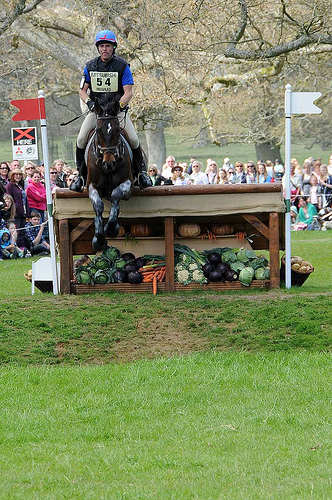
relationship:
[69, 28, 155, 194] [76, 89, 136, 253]
man riding horse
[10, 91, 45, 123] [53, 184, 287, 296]
red flag on hurdle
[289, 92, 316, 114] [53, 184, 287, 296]
flag on hurdle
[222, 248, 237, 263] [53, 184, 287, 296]
vegetable under hurdle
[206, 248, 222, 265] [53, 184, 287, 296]
vegetable under hurdle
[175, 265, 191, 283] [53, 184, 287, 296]
vegetable under hurdle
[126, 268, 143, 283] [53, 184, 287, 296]
vegetable under hurdle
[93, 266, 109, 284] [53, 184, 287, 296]
vegetable under hurdle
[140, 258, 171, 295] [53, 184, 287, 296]
carrots under hurdle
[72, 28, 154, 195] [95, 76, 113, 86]
man wearing number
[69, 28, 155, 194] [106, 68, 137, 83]
man has shirt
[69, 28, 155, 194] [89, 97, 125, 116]
man has black gloves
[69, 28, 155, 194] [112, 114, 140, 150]
man has pants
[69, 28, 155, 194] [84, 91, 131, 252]
man riding horse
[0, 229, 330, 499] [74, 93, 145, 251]
grass under horse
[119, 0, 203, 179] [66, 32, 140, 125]
tree behind rider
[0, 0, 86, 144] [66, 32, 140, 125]
tree behind rider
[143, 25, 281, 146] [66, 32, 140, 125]
tree behind rider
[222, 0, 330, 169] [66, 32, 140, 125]
tree behind rider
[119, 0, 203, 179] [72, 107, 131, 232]
tree behind horse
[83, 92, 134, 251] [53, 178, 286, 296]
horse jumping over stand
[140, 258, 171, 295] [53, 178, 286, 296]
carrots on stand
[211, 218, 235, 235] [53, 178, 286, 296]
pumpkin under stand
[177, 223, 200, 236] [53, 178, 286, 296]
pumpkin under stand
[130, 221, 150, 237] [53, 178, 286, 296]
pumpkin under stand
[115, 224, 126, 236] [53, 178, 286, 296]
pumpkin under stand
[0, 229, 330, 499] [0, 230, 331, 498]
grass in field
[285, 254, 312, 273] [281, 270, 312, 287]
potatoes in basket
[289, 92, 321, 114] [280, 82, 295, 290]
flag on stand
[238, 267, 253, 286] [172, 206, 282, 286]
cabbage in container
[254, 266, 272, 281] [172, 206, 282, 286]
cabbage in container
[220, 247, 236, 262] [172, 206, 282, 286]
cabbage in container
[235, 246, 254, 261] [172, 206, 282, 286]
cabbage in container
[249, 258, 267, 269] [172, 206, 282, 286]
cabbage in container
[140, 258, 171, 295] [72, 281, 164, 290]
carrots in container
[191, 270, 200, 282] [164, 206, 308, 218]
cauliflower head in container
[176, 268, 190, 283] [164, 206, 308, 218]
cauliflower head in container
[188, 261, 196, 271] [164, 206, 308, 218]
cauliflower head in container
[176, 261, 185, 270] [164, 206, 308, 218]
cauliflower head in container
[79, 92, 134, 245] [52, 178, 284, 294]
horse jumping over structure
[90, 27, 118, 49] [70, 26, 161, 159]
helmet on man.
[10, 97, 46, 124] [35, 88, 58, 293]
red flag on pole